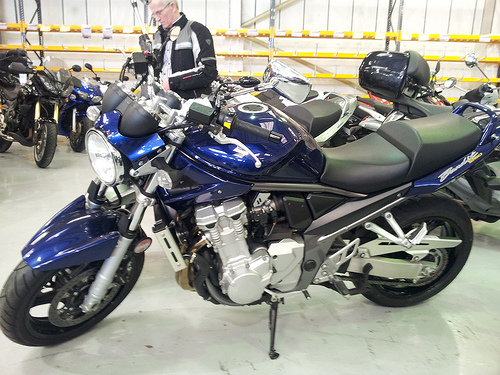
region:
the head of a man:
[130, 0, 174, 43]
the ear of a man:
[162, 0, 189, 18]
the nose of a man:
[143, 2, 188, 34]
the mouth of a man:
[156, 0, 182, 58]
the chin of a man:
[137, 14, 187, 40]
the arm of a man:
[156, 8, 254, 121]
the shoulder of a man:
[167, 12, 221, 54]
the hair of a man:
[139, 0, 193, 46]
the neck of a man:
[168, 3, 191, 48]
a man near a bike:
[34, 6, 279, 221]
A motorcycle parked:
[1, 39, 496, 361]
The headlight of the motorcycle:
[82, 124, 125, 191]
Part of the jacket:
[179, 53, 190, 64]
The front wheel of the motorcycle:
[0, 215, 146, 352]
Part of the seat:
[347, 153, 374, 176]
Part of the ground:
[24, 179, 38, 203]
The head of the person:
[148, 0, 185, 30]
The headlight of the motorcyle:
[38, 75, 79, 99]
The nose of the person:
[153, 12, 160, 23]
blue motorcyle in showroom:
[1, 57, 476, 353]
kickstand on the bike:
[256, 298, 290, 365]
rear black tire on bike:
[357, 190, 481, 325]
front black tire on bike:
[0, 219, 153, 350]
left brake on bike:
[211, 134, 265, 165]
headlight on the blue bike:
[73, 129, 125, 190]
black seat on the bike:
[315, 138, 406, 183]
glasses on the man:
[142, 1, 176, 17]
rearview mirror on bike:
[461, 50, 486, 82]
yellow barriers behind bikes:
[232, 31, 366, 78]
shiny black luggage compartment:
[357, 48, 410, 102]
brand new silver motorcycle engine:
[198, 208, 305, 303]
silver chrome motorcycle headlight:
[84, 123, 124, 188]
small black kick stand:
[267, 301, 281, 363]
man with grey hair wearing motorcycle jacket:
[134, 0, 219, 95]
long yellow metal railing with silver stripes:
[0, 22, 499, 40]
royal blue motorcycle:
[1, 73, 493, 363]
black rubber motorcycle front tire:
[31, 115, 59, 168]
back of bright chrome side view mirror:
[258, 58, 314, 105]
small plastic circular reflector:
[136, 230, 154, 260]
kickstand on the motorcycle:
[259, 288, 289, 367]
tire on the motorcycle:
[0, 243, 159, 347]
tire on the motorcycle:
[358, 188, 475, 311]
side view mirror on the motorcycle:
[263, 58, 310, 107]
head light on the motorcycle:
[80, 120, 119, 185]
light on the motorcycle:
[149, 170, 176, 188]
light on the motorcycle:
[82, 99, 103, 119]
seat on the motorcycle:
[317, 122, 409, 177]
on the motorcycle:
[236, 100, 270, 122]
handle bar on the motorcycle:
[221, 117, 288, 149]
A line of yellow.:
[294, 47, 316, 59]